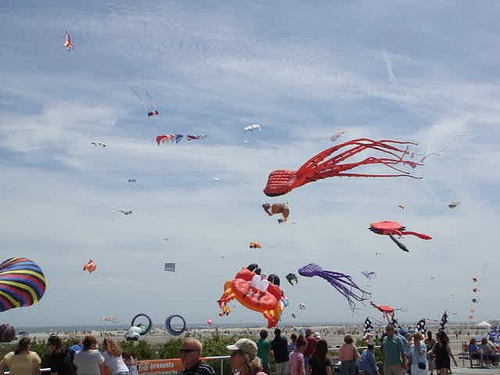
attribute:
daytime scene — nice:
[0, 2, 499, 373]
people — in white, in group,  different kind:
[0, 317, 498, 372]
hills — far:
[17, 323, 162, 337]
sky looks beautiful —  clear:
[1, 1, 499, 324]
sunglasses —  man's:
[174, 347, 198, 353]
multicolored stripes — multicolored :
[0, 255, 45, 312]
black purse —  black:
[413, 344, 428, 370]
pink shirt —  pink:
[285, 350, 308, 374]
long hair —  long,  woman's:
[244, 353, 263, 373]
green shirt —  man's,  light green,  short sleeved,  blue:
[379, 335, 403, 363]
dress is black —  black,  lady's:
[434, 333, 450, 374]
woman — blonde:
[98, 333, 131, 374]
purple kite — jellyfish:
[296, 262, 371, 315]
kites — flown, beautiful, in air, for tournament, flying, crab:
[2, 14, 474, 337]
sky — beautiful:
[8, 8, 470, 338]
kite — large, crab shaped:
[213, 259, 294, 330]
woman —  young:
[289, 330, 309, 373]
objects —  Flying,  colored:
[215, 140, 433, 327]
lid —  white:
[225, 336, 257, 355]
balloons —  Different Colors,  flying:
[215, 136, 430, 327]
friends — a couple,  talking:
[174, 332, 264, 372]